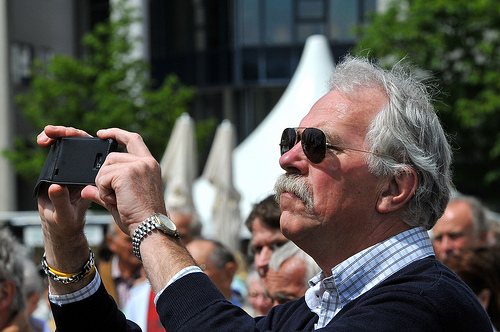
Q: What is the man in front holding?
A: A camera.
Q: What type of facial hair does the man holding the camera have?
A: A mustache.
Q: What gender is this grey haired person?
A: Male.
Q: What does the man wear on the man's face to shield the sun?
A: Sunglasses.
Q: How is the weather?
A: Sunny.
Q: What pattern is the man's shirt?
A: Checkered.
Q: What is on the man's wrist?
A: Watch.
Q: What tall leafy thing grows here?
A: Tree.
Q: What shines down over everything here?
A: Sun.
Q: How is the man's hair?
A: Loose.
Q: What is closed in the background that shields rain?
A: Umbrella.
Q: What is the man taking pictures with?
A: Phone.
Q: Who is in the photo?
A: A crowd of people.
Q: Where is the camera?
A: In the man's hands.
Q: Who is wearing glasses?
A: A man.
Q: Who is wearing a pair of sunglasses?
A: The man.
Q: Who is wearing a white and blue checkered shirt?
A: The man.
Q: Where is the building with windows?
A: Behind the people.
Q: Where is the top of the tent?
A: Behind the man.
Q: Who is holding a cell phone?
A: The man.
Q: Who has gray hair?
A: The man.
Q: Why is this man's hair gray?
A: He is elderly.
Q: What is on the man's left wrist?
A: A watch.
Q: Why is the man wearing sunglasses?
A: It is sunny.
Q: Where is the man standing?
A: Among the crowds.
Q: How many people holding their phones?
A: One.